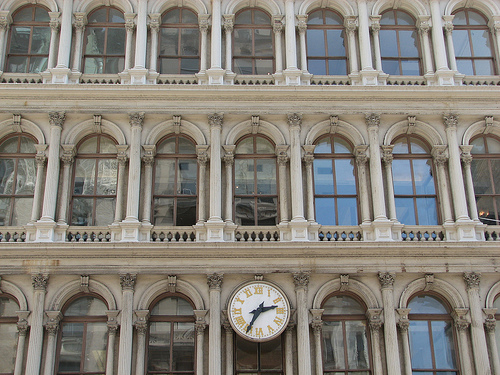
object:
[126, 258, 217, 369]
frames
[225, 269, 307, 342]
clock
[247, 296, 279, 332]
hands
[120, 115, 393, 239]
posts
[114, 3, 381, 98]
next floor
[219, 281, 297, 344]
clock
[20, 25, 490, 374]
building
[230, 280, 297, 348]
clock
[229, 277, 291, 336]
numerals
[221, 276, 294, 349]
clock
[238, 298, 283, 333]
hands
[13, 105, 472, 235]
windows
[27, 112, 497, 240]
windows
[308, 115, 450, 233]
windows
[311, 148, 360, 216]
sky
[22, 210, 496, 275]
balconies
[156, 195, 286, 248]
railings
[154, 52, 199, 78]
boxes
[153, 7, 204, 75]
windows